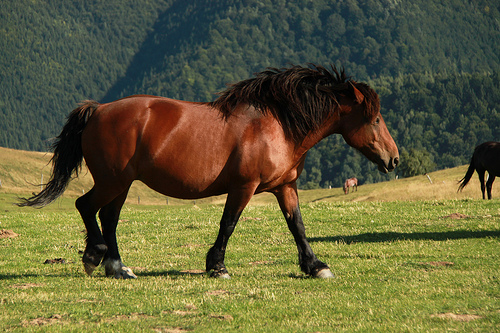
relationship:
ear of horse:
[348, 77, 365, 103] [12, 62, 401, 287]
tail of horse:
[4, 95, 100, 205] [14, 62, 400, 280]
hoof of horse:
[308, 262, 335, 279] [12, 62, 401, 287]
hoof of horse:
[205, 263, 230, 280] [12, 62, 401, 287]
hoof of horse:
[105, 267, 139, 279] [12, 62, 401, 287]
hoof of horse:
[82, 251, 105, 276] [12, 62, 401, 287]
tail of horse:
[10, 100, 101, 210] [12, 62, 401, 287]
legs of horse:
[77, 209, 336, 284] [32, 38, 427, 300]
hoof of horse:
[313, 265, 333, 280] [12, 62, 401, 287]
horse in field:
[455, 139, 499, 199] [2, 154, 497, 326]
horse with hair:
[12, 62, 401, 287] [15, 100, 95, 210]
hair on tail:
[15, 100, 95, 210] [14, 100, 95, 214]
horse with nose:
[343, 177, 358, 194] [388, 154, 404, 165]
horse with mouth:
[12, 62, 401, 287] [380, 162, 398, 175]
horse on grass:
[14, 62, 400, 280] [307, 181, 397, 222]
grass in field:
[234, 228, 291, 300] [2, 154, 497, 326]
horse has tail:
[455, 139, 499, 199] [459, 142, 481, 192]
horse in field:
[12, 62, 401, 287] [2, 154, 497, 326]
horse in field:
[14, 62, 400, 280] [2, 154, 497, 326]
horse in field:
[335, 171, 363, 192] [2, 154, 497, 326]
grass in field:
[368, 211, 475, 328] [11, 111, 497, 317]